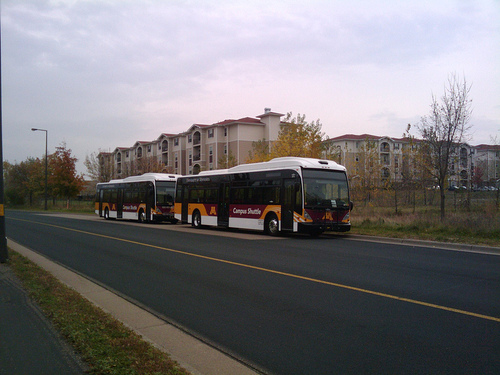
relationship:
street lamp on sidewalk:
[31, 128, 49, 211] [39, 211, 102, 221]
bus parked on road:
[173, 156, 354, 236] [158, 230, 488, 332]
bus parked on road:
[92, 169, 184, 215] [158, 230, 488, 332]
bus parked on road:
[94, 172, 184, 223] [8, 206, 498, 370]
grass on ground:
[30, 281, 141, 373] [4, 272, 97, 369]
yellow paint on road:
[2, 207, 497, 328] [8, 206, 498, 370]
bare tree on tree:
[418, 73, 477, 224] [406, 79, 478, 222]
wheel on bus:
[264, 211, 279, 237] [178, 147, 365, 258]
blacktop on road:
[4, 204, 484, 362] [241, 317, 373, 358]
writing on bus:
[226, 201, 267, 220] [177, 160, 352, 232]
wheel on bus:
[185, 207, 205, 229] [169, 152, 353, 236]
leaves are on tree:
[258, 114, 348, 157] [277, 100, 322, 162]